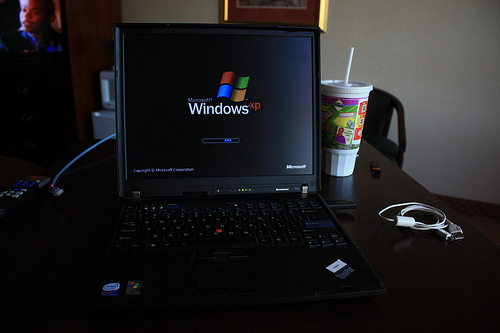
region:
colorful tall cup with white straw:
[315, 22, 416, 187]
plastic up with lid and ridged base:
[322, 75, 382, 180]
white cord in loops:
[375, 190, 470, 250]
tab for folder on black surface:
[302, 236, 363, 291]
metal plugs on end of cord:
[425, 200, 465, 250]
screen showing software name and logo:
[100, 16, 340, 201]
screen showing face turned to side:
[5, 0, 70, 60]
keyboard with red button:
[105, 180, 360, 265]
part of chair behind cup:
[330, 70, 435, 170]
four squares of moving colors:
[215, 61, 255, 106]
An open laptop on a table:
[97, 17, 392, 298]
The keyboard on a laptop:
[104, 193, 350, 251]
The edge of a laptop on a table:
[305, 190, 394, 302]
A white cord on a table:
[380, 184, 463, 275]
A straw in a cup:
[338, 39, 364, 84]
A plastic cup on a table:
[323, 67, 373, 194]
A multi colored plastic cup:
[324, 74, 378, 196]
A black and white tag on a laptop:
[300, 247, 368, 279]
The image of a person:
[12, 2, 69, 55]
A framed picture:
[217, 3, 354, 34]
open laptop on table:
[100, 17, 383, 314]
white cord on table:
[371, 196, 465, 245]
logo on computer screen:
[181, 66, 265, 125]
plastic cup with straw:
[316, 42, 393, 186]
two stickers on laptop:
[97, 273, 154, 305]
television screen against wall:
[10, 3, 68, 66]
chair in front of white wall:
[366, 59, 413, 162]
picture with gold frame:
[213, 1, 338, 38]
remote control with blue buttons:
[0, 166, 56, 217]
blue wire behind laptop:
[62, 134, 112, 171]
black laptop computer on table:
[53, 94, 433, 281]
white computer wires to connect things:
[365, 186, 468, 261]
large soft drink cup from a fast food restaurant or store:
[320, 41, 381, 188]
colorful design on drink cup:
[329, 101, 367, 148]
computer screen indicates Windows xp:
[170, 60, 272, 159]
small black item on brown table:
[363, 139, 390, 188]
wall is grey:
[400, 21, 472, 167]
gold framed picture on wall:
[205, 0, 357, 35]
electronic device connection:
[6, 145, 84, 225]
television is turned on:
[7, 0, 92, 115]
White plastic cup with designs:
[305, 37, 378, 192]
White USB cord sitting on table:
[371, 177, 476, 244]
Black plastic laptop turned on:
[89, 15, 399, 327]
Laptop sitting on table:
[66, 7, 376, 331]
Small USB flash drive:
[362, 151, 394, 185]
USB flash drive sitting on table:
[355, 147, 396, 191]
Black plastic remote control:
[1, 157, 63, 207]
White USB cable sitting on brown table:
[368, 179, 478, 252]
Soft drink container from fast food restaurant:
[303, 34, 380, 188]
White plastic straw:
[337, 38, 359, 92]